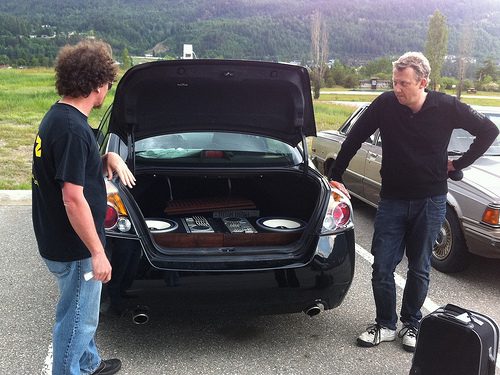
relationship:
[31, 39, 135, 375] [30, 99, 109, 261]
friend in shirt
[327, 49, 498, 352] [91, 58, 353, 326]
guy inside car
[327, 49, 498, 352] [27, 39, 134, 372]
guy showing h friend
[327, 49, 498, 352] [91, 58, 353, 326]
guy beside car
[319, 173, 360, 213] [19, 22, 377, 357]
hand on car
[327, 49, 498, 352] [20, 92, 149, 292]
guy wearing t-shirt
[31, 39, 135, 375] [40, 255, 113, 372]
friend wearing jeans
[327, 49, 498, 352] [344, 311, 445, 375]
guy wearing shoes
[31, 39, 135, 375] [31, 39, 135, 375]
friend on a friend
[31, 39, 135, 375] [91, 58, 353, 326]
friend near a car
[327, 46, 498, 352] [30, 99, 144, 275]
guy wears shirt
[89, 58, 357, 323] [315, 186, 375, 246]
black car with taillights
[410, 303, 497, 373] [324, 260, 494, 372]
luggage on ground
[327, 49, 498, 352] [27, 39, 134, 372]
guy showing friend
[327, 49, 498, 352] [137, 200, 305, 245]
guy showing speakers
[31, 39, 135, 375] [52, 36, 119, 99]
friend with curly hair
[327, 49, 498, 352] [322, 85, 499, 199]
guy in dark shirt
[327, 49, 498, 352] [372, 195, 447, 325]
guy in blue jeans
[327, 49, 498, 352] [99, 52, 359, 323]
guy to right of black car